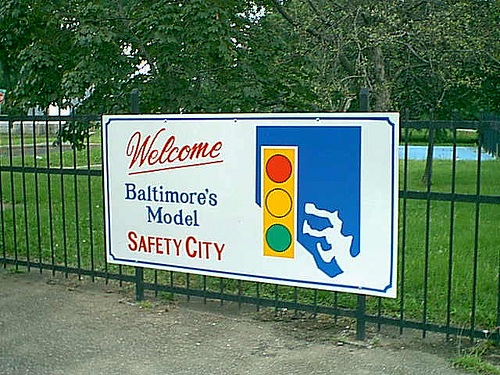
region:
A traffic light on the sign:
[262, 147, 296, 260]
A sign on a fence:
[103, 116, 395, 296]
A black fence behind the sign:
[8, 125, 99, 272]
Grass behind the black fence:
[436, 209, 443, 306]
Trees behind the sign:
[118, 17, 406, 92]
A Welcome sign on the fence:
[102, 118, 399, 298]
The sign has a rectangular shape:
[102, 115, 397, 299]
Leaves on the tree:
[417, 15, 483, 96]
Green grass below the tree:
[434, 199, 442, 294]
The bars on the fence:
[418, 142, 455, 277]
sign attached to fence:
[106, 113, 395, 296]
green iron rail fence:
[1, 100, 498, 347]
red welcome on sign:
[119, 127, 223, 169]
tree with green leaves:
[0, 2, 499, 135]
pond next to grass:
[401, 141, 495, 161]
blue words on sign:
[126, 183, 218, 226]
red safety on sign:
[126, 230, 181, 256]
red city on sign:
[186, 237, 225, 262]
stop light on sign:
[263, 146, 296, 258]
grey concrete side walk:
[5, 273, 499, 374]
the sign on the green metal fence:
[99, 109, 401, 295]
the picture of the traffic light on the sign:
[259, 143, 295, 255]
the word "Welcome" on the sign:
[123, 126, 223, 168]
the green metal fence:
[4, 88, 499, 340]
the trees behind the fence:
[2, 0, 494, 192]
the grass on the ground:
[6, 148, 498, 338]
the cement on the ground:
[4, 256, 441, 367]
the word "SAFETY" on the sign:
[126, 228, 183, 259]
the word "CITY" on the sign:
[184, 235, 224, 262]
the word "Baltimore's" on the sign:
[123, 181, 217, 206]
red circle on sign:
[264, 155, 296, 182]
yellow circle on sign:
[266, 189, 295, 217]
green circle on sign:
[266, 225, 291, 252]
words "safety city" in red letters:
[123, 229, 225, 264]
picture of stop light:
[261, 146, 297, 256]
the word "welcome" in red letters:
[123, 127, 226, 172]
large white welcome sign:
[98, 110, 398, 299]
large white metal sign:
[101, 109, 398, 299]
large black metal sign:
[0, 109, 498, 347]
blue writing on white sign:
[123, 178, 218, 230]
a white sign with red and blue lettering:
[102, 117, 397, 297]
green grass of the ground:
[413, 227, 488, 313]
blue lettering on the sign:
[108, 178, 230, 239]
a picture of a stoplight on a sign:
[247, 145, 306, 275]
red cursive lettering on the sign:
[118, 123, 232, 165]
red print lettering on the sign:
[115, 230, 240, 268]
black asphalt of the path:
[16, 303, 235, 363]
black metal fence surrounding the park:
[13, 116, 115, 271]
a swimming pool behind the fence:
[380, 124, 492, 169]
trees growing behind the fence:
[52, 1, 470, 109]